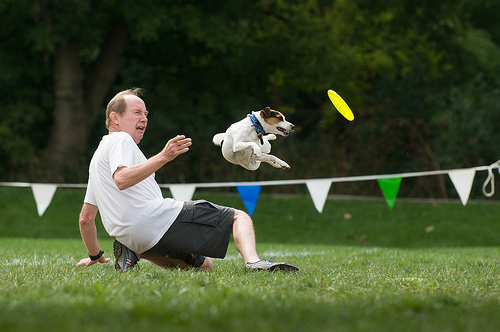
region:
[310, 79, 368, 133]
a bright yellow frisbee midair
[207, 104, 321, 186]
a dog jumping into the air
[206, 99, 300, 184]
a white and brown dog wearing a collar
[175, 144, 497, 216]
a multi-colored flag banner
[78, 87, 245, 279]
a man in a white shirt and shorts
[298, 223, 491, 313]
well kept green grass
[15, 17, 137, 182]
a tree with a split trunk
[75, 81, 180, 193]
a man making an odd face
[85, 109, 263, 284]
a man kneeling to the ground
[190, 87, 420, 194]
a dog trying to catch a frisbee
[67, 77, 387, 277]
Man is on ground throwing frisbee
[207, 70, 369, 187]
Dog is in air catching frisbee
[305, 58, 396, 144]
Yellow frisbee is in the air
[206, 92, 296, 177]
The dog is wearing a collar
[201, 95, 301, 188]
The dog is white and brown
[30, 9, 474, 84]
There are trees in the background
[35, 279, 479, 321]
There is grass under the man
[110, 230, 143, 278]
The shoes have an N on them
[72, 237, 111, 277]
The man is wearing a watch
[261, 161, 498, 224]
There is a rope with flags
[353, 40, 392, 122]
a tree in a distance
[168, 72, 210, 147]
a tree in a distance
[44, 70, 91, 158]
a tree in a distance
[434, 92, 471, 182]
a tree in a distance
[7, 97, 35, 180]
a tree in a distance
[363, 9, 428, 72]
a tree in a distance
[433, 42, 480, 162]
a tree in a distance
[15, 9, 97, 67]
a tree in a distance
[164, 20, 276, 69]
a tree in a distance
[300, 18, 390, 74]
a tree in a distance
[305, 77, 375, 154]
a yellow frisbee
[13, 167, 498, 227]
a multi colored triangle banner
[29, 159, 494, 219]
triangle banner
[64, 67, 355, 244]
a man and a dog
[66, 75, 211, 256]
a man wearing a white shirt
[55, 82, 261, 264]
a man wearing black shorts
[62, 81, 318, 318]
a man wearing athletic sneakers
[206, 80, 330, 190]
a small dog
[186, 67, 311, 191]
a small dog wearing a collar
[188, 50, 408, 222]
a small dog playing with a yellow frisbee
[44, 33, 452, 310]
Man and dog playing with frisbee.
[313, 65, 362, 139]
Yellow frisbee in the air.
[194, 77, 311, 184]
Dog jumping through the air.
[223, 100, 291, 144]
Blue collar around dog's neck.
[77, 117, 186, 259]
White short sleeve tee shirt.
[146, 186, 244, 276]
A pair of dark shorts.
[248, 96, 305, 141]
The dog's head is brown and white.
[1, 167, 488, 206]
A string of pennant flags.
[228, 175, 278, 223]
Blue flag on string of flags.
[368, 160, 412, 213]
Green flag on string of flags.